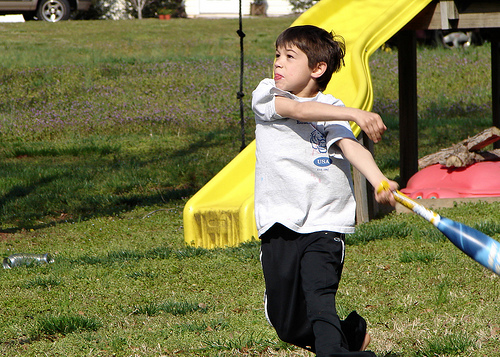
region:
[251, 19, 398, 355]
Young Boy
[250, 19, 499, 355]
Young boy swinging a baseball bat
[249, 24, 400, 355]
Young boy wearing black pants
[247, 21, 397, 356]
Young boy wearing a white t-shirt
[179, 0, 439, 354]
A yellow slide behind a young boy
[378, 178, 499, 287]
Baseball bat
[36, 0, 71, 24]
Car Wheel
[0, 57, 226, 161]
Small purple flowers in grassy lawn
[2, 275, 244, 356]
Grassy landscape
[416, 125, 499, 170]
Two pieces of wooden logs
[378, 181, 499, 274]
yellow and blue bat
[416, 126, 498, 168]
two pieces of chopped wood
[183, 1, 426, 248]
yellow slide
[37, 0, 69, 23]
one car tire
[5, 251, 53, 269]
silver, metal tube on the ground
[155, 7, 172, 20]
two plants in orange pots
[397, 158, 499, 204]
red plastic dome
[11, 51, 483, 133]
patch of small purple flowers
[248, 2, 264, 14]
brown box in the background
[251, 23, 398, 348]
boy swinging a bat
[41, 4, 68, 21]
shiny hubcap of a car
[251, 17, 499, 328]
little boy playing baseball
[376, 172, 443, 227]
yellow tip of a baseball bat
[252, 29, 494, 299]
little boy holding a baseball bat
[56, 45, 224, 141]
purple flowers on the grass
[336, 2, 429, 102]
a yellow slide in a park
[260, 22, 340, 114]
little boy sticking out his tongue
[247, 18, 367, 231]
little boy wearing a white shirt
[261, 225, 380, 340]
little boy wearing black pants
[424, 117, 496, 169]
two logs of wood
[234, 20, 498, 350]
a boy swinging a bat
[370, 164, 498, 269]
a bat in a boy's hand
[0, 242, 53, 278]
a slinky in the grass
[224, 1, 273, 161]
a rope swing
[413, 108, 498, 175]
logs on a sandbox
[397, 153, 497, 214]
a covered sandbox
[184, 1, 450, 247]
a yellow plastic slide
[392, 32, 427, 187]
a post support a jungle gym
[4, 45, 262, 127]
a swath of purple flowers in the grass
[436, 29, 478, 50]
a mask in the shadows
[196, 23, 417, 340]
the boy swinging the baseball bat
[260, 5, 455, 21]
the yellow swing you can swing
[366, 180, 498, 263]
the baseball bat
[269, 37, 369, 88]
the face of the boy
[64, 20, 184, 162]
green grass in the park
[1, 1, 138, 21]
the car parked on the side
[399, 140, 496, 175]
logs on top of the toy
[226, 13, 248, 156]
a black rope by the slide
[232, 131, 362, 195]
the kids grey shirt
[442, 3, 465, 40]
the bottom of the deck